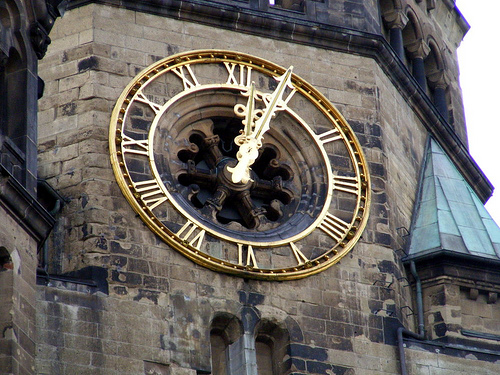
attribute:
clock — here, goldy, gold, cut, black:
[112, 55, 354, 259]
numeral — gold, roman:
[153, 53, 237, 95]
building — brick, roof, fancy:
[60, 77, 88, 135]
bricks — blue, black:
[370, 25, 396, 39]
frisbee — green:
[102, 345, 173, 367]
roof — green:
[384, 122, 470, 254]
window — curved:
[256, 298, 284, 341]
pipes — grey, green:
[19, 103, 52, 192]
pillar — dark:
[393, 29, 401, 70]